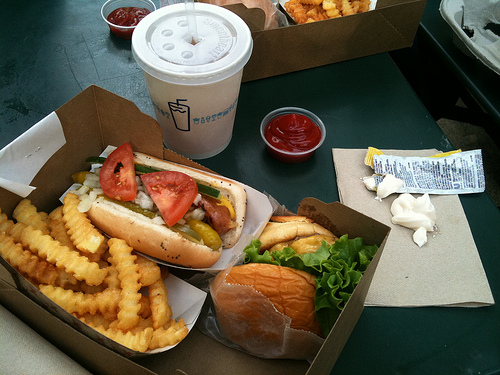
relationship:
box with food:
[241, 1, 424, 82] [284, 0, 374, 23]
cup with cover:
[146, 67, 246, 160] [129, 0, 254, 87]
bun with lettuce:
[212, 263, 321, 347] [240, 235, 379, 317]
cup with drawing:
[146, 67, 246, 160] [169, 98, 189, 132]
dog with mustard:
[74, 143, 247, 269] [217, 196, 237, 217]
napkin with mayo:
[332, 147, 495, 308] [390, 191, 435, 248]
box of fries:
[241, 1, 424, 82] [284, 0, 374, 23]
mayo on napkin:
[390, 191, 435, 248] [332, 147, 495, 308]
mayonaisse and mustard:
[365, 146, 487, 194] [364, 146, 462, 191]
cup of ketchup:
[259, 107, 326, 162] [264, 112, 322, 152]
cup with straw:
[146, 67, 246, 160] [184, 0, 197, 44]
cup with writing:
[146, 67, 246, 160] [191, 96, 239, 128]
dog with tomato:
[72, 171, 230, 233] [98, 142, 139, 204]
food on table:
[284, 0, 374, 23] [194, 52, 447, 215]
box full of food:
[241, 1, 424, 82] [284, 0, 374, 23]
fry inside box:
[107, 236, 142, 329] [0, 84, 392, 375]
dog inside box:
[72, 171, 230, 233] [0, 84, 392, 375]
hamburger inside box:
[211, 214, 373, 357] [0, 84, 392, 375]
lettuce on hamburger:
[240, 235, 379, 317] [211, 214, 373, 357]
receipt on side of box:
[0, 110, 68, 198] [0, 84, 392, 375]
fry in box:
[107, 236, 142, 329] [0, 84, 392, 375]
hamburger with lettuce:
[211, 214, 373, 357] [240, 235, 379, 317]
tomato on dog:
[98, 142, 139, 204] [72, 171, 230, 233]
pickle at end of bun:
[73, 169, 93, 185] [73, 151, 246, 268]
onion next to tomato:
[136, 192, 153, 208] [98, 142, 139, 204]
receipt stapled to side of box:
[0, 110, 68, 198] [0, 84, 392, 375]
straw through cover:
[184, 0, 197, 44] [129, 0, 254, 87]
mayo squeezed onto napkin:
[390, 191, 435, 248] [332, 147, 495, 308]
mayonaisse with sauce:
[373, 150, 483, 194] [377, 174, 402, 201]